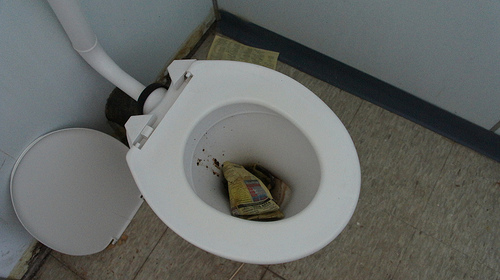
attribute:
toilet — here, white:
[123, 57, 365, 268]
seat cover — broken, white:
[7, 125, 146, 257]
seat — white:
[127, 63, 362, 266]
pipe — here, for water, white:
[47, 0, 146, 100]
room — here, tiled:
[1, 1, 500, 279]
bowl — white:
[183, 101, 323, 223]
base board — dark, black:
[213, 8, 499, 162]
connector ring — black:
[137, 82, 169, 114]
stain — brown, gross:
[212, 156, 220, 169]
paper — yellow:
[206, 33, 281, 71]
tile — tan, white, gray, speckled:
[387, 228, 499, 279]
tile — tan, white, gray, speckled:
[416, 143, 499, 272]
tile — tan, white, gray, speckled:
[346, 99, 456, 229]